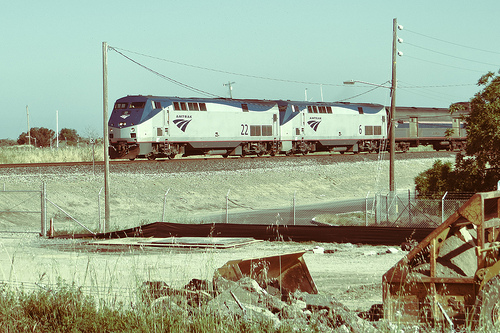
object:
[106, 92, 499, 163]
train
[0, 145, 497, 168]
tracks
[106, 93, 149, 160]
front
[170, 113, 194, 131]
logo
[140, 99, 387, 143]
side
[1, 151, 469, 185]
rocks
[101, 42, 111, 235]
pole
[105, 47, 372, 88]
line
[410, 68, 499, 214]
shrub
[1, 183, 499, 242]
fence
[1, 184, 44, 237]
gate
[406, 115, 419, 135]
compartment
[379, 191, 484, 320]
front end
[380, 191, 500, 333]
bulldozer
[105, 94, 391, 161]
engine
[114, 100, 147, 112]
windshield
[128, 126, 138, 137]
headlight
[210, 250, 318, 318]
bin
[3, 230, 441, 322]
road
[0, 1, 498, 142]
sky